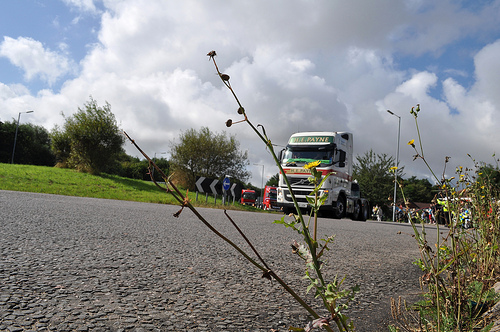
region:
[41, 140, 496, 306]
image is taken outdoors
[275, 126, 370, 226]
a truck is on the road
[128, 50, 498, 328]
weeds and flowers are on the roadside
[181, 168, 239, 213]
a directional sign is on the side of the road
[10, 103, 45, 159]
a streetlight is behind the trees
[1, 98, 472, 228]
green trees are on the hillside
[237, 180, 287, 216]
two red trucks are on the road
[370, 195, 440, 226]
a group of people are on the roadside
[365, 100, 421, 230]
a street lamp is above the people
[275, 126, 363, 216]
the cab of the truck is white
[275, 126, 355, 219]
the truck has a red stripe and a green stripe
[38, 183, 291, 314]
concrete is grey and jagged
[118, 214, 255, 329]
concrete is grey and jagged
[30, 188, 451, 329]
street is grey concrete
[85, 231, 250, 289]
street is grey concrete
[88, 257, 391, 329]
street is grey concrete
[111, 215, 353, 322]
street is grey concrete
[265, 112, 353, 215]
truck is green and white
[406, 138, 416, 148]
yellow flower on the plant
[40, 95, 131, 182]
green bush on the lawn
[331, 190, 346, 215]
black tire on the truck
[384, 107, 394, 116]
street light on the pole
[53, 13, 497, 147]
large clouds in the sky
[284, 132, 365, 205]
a white truck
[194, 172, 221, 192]
a black and white sign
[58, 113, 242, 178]
trees next to the road